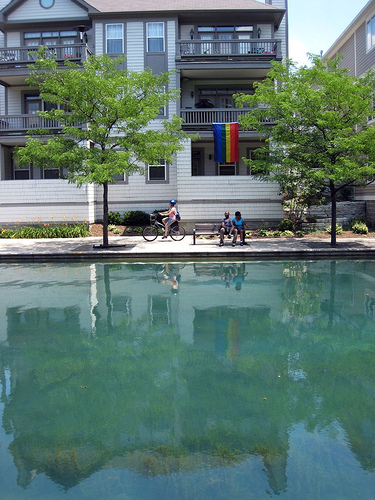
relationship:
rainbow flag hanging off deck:
[212, 123, 237, 162] [182, 100, 276, 127]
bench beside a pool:
[187, 223, 245, 241] [3, 258, 374, 499]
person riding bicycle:
[163, 202, 178, 234] [143, 215, 185, 239]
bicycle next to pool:
[143, 215, 185, 239] [3, 258, 374, 499]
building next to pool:
[2, 1, 292, 226] [3, 258, 374, 499]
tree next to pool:
[19, 47, 184, 248] [3, 258, 374, 499]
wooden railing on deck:
[179, 111, 282, 122] [182, 100, 276, 127]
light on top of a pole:
[187, 29, 195, 33] [189, 35, 194, 42]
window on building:
[145, 23, 164, 52] [2, 1, 292, 226]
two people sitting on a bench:
[221, 212, 244, 243] [187, 223, 245, 241]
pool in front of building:
[3, 258, 374, 499] [2, 1, 292, 226]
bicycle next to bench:
[143, 215, 185, 239] [187, 223, 245, 241]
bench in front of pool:
[187, 223, 245, 241] [3, 258, 374, 499]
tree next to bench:
[19, 47, 184, 248] [187, 223, 245, 241]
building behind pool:
[2, 1, 292, 226] [3, 258, 374, 499]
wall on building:
[95, 22, 175, 204] [2, 1, 292, 226]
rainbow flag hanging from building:
[212, 123, 237, 162] [2, 1, 292, 226]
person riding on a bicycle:
[163, 202, 178, 234] [143, 215, 185, 239]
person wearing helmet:
[163, 202, 178, 234] [169, 198, 181, 206]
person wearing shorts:
[163, 202, 178, 234] [164, 218, 175, 228]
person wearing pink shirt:
[163, 202, 178, 234] [169, 210, 177, 218]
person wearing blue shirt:
[232, 210, 246, 240] [234, 220, 242, 227]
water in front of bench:
[3, 258, 374, 499] [187, 223, 245, 241]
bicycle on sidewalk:
[143, 215, 185, 239] [6, 238, 374, 255]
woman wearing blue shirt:
[232, 210, 246, 240] [234, 220, 242, 227]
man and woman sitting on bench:
[221, 212, 244, 243] [187, 223, 245, 241]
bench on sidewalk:
[187, 223, 245, 241] [6, 238, 374, 255]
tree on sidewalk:
[19, 47, 184, 248] [6, 238, 374, 255]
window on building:
[107, 27, 124, 53] [2, 1, 292, 226]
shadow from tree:
[35, 238, 100, 250] [19, 47, 184, 248]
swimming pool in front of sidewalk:
[3, 258, 374, 499] [6, 238, 374, 255]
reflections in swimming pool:
[141, 261, 264, 308] [3, 258, 374, 499]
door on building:
[218, 27, 234, 52] [2, 1, 292, 226]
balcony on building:
[182, 100, 276, 127] [2, 1, 292, 226]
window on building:
[145, 147, 168, 179] [2, 1, 292, 226]